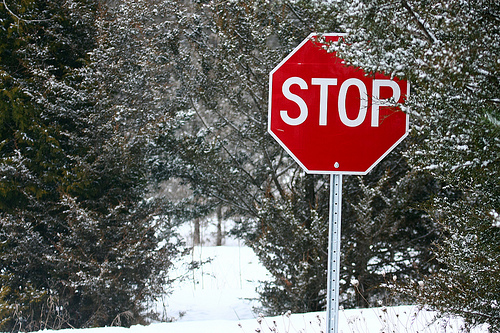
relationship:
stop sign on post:
[263, 21, 423, 175] [321, 172, 342, 332]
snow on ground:
[2, 2, 498, 330] [0, 201, 498, 331]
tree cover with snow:
[3, 0, 220, 332] [40, 12, 222, 324]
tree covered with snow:
[119, 24, 380, 322] [125, 29, 285, 283]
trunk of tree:
[214, 199, 224, 249] [91, 3, 238, 244]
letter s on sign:
[278, 77, 309, 127] [267, 28, 415, 178]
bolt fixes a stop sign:
[328, 159, 343, 171] [263, 21, 423, 175]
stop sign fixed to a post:
[263, 21, 423, 175] [321, 172, 342, 332]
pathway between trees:
[158, 237, 253, 327] [66, 30, 268, 170]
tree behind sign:
[267, 1, 497, 331] [267, 28, 415, 178]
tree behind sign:
[103, 0, 295, 243] [267, 28, 415, 178]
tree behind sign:
[3, 0, 220, 332] [267, 28, 415, 178]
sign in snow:
[268, 30, 409, 331] [2, 209, 497, 331]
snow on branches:
[2, 2, 498, 330] [4, 2, 498, 331]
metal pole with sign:
[311, 176, 376, 325] [233, 13, 439, 201]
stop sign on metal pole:
[263, 21, 423, 175] [317, 172, 350, 333]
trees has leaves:
[0, 0, 500, 332] [2, 1, 499, 330]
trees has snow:
[0, 0, 500, 332] [2, 2, 498, 330]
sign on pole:
[267, 28, 415, 178] [322, 173, 344, 330]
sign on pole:
[268, 30, 409, 331] [326, 173, 343, 330]